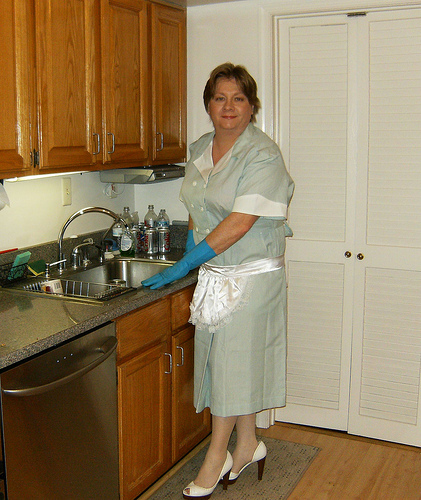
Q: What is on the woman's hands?
A: Blue gloves.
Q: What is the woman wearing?
A: Maid uniform.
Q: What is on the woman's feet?
A: High heels.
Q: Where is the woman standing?
A: Kitchen.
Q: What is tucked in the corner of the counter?
A: Empty bottles and cans.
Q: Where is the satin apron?
A: Woman's waist.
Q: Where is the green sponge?
A: Rack over sink.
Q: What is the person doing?
A: Washing dishes.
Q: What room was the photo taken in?
A: Kitchen.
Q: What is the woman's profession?
A: Maid.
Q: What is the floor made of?
A: Wood.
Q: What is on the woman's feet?
A: White heels.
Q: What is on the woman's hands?
A: Blue rubber gloves.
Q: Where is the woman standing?
A: In front of the sink.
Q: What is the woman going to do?
A: Wash dishes.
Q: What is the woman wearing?
A: Maid's uniform.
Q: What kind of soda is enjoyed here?
A: Diet Coke.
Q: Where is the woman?
A: In the kitchen.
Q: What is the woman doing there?
A: Cleaning.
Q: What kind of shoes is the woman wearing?
A: High heels.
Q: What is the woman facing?
A: The camera.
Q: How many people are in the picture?
A: One.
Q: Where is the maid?
A: Kitchen.